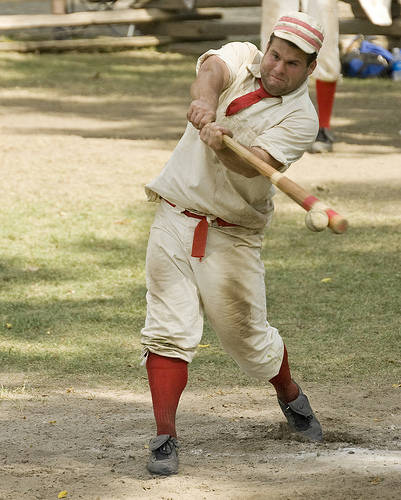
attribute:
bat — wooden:
[220, 130, 352, 241]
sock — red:
[141, 345, 193, 442]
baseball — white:
[304, 210, 329, 232]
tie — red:
[225, 77, 277, 126]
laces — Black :
[155, 438, 180, 460]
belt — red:
[162, 197, 241, 255]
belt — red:
[157, 193, 251, 258]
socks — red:
[141, 348, 299, 432]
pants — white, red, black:
[137, 192, 284, 382]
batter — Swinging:
[134, 11, 349, 477]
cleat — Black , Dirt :
[129, 424, 190, 474]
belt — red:
[147, 189, 267, 260]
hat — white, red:
[269, 7, 326, 57]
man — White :
[201, 18, 352, 287]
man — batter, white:
[123, 23, 377, 470]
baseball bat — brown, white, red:
[227, 137, 347, 233]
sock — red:
[126, 357, 204, 426]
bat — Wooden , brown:
[222, 135, 349, 235]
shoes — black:
[134, 389, 323, 473]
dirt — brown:
[9, 390, 125, 494]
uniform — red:
[125, 39, 320, 386]